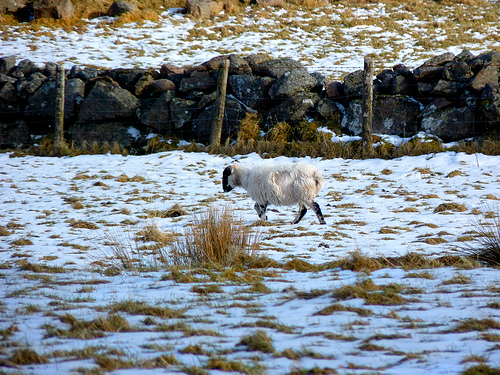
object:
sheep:
[221, 157, 331, 224]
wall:
[0, 57, 500, 153]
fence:
[0, 54, 499, 147]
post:
[211, 59, 232, 150]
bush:
[240, 110, 338, 161]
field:
[0, 128, 500, 375]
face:
[222, 166, 232, 193]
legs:
[305, 198, 326, 226]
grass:
[103, 229, 144, 282]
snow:
[0, 150, 500, 375]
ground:
[0, 151, 500, 375]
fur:
[296, 177, 315, 205]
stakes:
[361, 56, 374, 154]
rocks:
[0, 55, 50, 120]